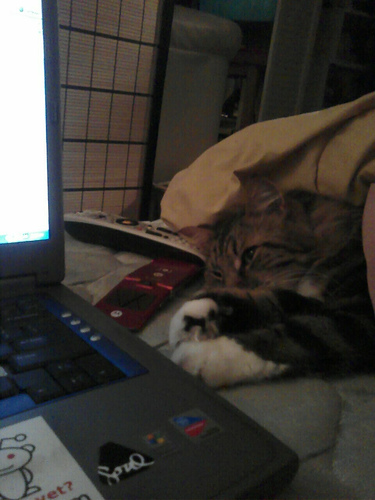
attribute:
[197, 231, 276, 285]
eyes — green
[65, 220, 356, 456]
matress — gray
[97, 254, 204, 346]
flip phone — red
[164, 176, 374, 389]
cat — striped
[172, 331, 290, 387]
paw — white, cat's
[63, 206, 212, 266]
remote — tv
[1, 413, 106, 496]
sticker — reddit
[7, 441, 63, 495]
logo — reddit, alien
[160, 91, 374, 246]
blanket — yellow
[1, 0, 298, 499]
computer — laptop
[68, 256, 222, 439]
logo — windows, microsoft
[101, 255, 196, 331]
phone — red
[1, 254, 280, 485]
computer — laptop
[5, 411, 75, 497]
logo — reddit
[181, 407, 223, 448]
logo — intel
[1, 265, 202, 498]
computer — laptop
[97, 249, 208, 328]
phone — cell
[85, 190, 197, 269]
control — remote, television